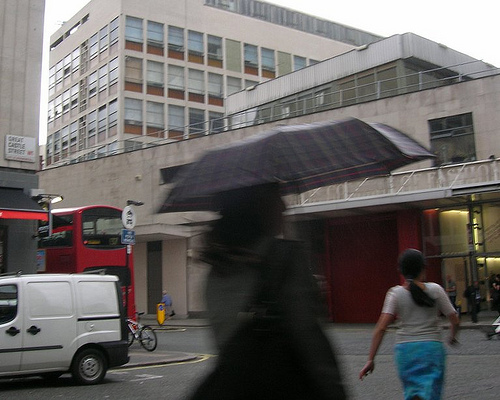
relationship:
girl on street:
[359, 248, 460, 399] [0, 316, 498, 398]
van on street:
[0, 272, 129, 383] [0, 316, 498, 398]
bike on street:
[126, 310, 159, 351] [0, 316, 498, 398]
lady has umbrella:
[201, 186, 349, 400] [156, 114, 434, 214]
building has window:
[48, 2, 387, 171] [127, 15, 145, 53]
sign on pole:
[120, 227, 136, 247] [124, 249, 130, 344]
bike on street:
[126, 310, 159, 351] [0, 363, 218, 399]